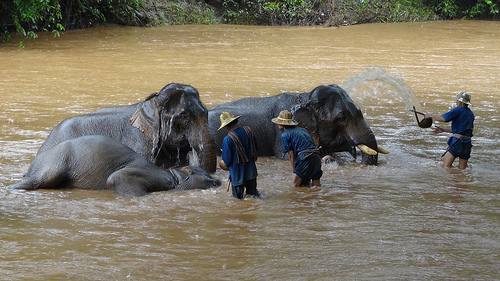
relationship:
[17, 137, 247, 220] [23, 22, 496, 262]
elephant laying river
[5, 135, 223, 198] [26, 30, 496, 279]
elephant sitting water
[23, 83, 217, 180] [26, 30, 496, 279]
elephant sitting water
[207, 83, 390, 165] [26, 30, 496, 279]
elephant sitting water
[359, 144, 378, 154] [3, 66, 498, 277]
tusk in water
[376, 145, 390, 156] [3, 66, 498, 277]
tusk in water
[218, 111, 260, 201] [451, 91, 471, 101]
men wearing a straw hats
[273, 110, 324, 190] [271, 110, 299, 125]
men wearing a hat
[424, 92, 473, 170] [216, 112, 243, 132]
man wearing a hat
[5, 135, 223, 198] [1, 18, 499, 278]
elephant is bathing river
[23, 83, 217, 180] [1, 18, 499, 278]
elephant is bathing river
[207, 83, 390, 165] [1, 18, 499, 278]
elephant is bathing river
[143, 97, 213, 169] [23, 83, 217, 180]
water streaming down elephant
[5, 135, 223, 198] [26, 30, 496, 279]
elephant in water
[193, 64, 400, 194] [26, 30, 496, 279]
elephant in water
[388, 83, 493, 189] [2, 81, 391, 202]
man is splashing elephants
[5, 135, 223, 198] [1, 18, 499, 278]
elephant laying in river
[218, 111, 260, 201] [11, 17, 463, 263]
men in river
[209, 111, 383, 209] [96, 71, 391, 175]
men in front of elephants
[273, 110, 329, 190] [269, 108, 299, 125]
men wearing hat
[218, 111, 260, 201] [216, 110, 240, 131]
men wearing hat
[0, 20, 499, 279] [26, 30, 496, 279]
ripples in water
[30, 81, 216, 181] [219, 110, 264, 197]
elephant looking at man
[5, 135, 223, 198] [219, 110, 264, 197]
elephant looking at man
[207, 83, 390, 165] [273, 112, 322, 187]
elephant looking at man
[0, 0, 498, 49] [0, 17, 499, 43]
trees on bank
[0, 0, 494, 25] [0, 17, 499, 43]
shrubs on bank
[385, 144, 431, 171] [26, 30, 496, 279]
waves in water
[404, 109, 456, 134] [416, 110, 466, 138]
water holder in hand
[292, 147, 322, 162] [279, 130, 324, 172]
sash around waist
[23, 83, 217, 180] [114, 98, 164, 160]
elephant has ear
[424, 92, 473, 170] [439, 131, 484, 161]
man wearing shorts